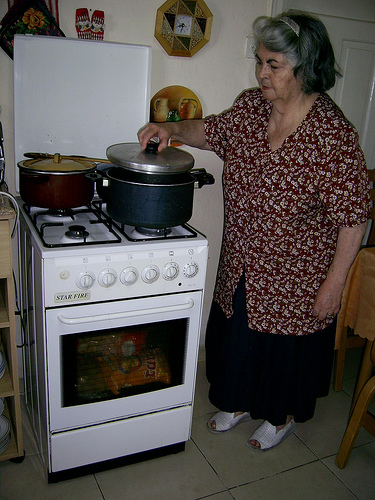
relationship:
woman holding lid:
[139, 11, 367, 447] [106, 136, 194, 175]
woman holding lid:
[139, 11, 367, 447] [106, 138, 195, 171]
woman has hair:
[139, 11, 367, 447] [253, 10, 314, 59]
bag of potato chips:
[96, 346, 169, 389] [99, 346, 168, 396]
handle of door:
[57, 298, 202, 328] [42, 284, 210, 438]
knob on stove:
[182, 262, 199, 276] [11, 183, 210, 470]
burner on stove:
[35, 212, 119, 246] [20, 188, 210, 484]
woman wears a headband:
[139, 11, 367, 447] [270, 14, 308, 42]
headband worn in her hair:
[270, 14, 308, 42] [251, 11, 345, 101]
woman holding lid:
[139, 11, 367, 447] [106, 140, 193, 175]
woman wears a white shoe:
[139, 11, 367, 447] [247, 412, 299, 454]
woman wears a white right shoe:
[139, 11, 367, 447] [209, 402, 247, 434]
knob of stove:
[75, 272, 96, 291] [11, 183, 210, 470]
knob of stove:
[99, 273, 119, 289] [11, 183, 210, 470]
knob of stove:
[119, 264, 139, 283] [11, 183, 210, 470]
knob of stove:
[141, 262, 160, 286] [11, 183, 210, 470]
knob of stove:
[162, 262, 178, 280] [11, 183, 210, 470]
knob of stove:
[182, 262, 199, 276] [11, 183, 210, 470]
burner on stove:
[35, 212, 119, 246] [6, 175, 217, 485]